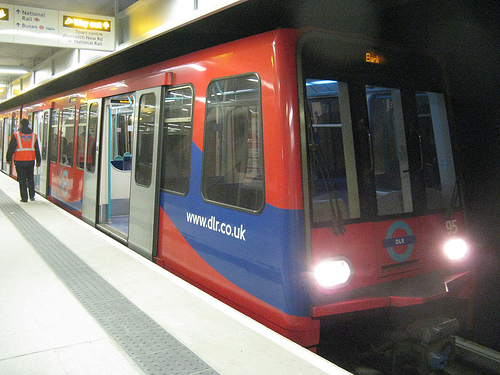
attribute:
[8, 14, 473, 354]
train — red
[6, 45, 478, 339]
subway — red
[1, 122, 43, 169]
sweater — black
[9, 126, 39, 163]
vest — orange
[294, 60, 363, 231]
window — glassy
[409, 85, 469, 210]
window — glassy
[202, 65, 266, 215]
window — glassy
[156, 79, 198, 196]
window — glassy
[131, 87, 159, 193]
window — glassy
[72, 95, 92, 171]
window — glassy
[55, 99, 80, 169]
window — glassy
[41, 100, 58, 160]
window — glassy